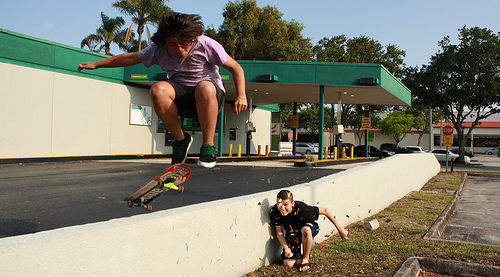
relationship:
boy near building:
[122, 9, 258, 161] [0, 29, 112, 184]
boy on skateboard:
[122, 9, 258, 161] [121, 153, 201, 221]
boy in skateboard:
[122, 9, 258, 161] [121, 153, 201, 221]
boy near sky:
[122, 9, 258, 161] [375, 3, 459, 42]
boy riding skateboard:
[122, 9, 258, 161] [121, 153, 201, 221]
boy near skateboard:
[122, 9, 258, 161] [121, 153, 201, 221]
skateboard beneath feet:
[130, 165, 186, 206] [162, 129, 218, 172]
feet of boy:
[162, 129, 218, 172] [75, 12, 251, 168]